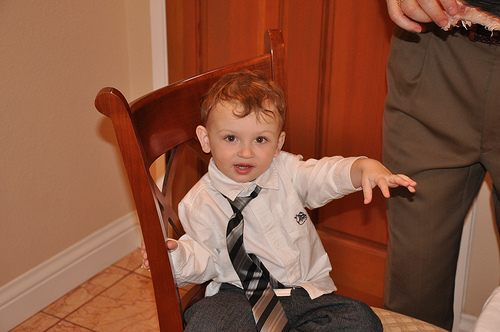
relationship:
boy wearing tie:
[142, 69, 420, 330] [219, 187, 287, 331]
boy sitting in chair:
[142, 69, 420, 330] [94, 29, 296, 329]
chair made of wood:
[94, 29, 296, 329] [96, 28, 290, 331]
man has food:
[383, 2, 495, 330] [443, 0, 497, 33]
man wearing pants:
[383, 2, 495, 330] [384, 24, 498, 325]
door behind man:
[164, 1, 396, 307] [383, 2, 495, 330]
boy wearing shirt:
[142, 69, 420, 330] [167, 151, 362, 300]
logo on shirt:
[293, 210, 306, 223] [167, 151, 362, 300]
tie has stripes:
[219, 187, 287, 331] [222, 194, 288, 331]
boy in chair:
[142, 69, 420, 330] [94, 29, 296, 329]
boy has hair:
[142, 69, 420, 330] [201, 67, 284, 132]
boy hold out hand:
[142, 69, 420, 330] [351, 158, 415, 204]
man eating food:
[383, 2, 495, 330] [443, 0, 497, 33]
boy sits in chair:
[142, 69, 420, 330] [94, 29, 296, 329]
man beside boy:
[383, 2, 495, 330] [142, 69, 420, 330]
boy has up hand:
[142, 69, 420, 330] [351, 158, 415, 204]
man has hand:
[383, 2, 495, 330] [386, 0, 457, 33]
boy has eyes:
[142, 69, 420, 330] [223, 134, 266, 144]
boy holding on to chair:
[142, 69, 420, 330] [94, 29, 296, 329]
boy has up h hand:
[142, 69, 420, 330] [351, 158, 415, 204]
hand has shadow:
[351, 158, 415, 204] [357, 192, 392, 226]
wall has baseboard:
[1, 0, 165, 328] [1, 212, 147, 331]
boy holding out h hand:
[142, 69, 420, 330] [351, 158, 415, 204]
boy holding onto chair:
[142, 69, 420, 330] [94, 29, 296, 329]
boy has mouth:
[142, 69, 420, 330] [232, 162, 257, 174]